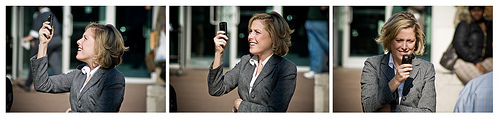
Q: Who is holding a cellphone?
A: The woman.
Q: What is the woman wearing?
A: A grey jacket.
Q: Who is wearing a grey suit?
A: The woman.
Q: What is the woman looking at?
A: Cellphone.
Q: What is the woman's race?
A: White.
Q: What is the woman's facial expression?
A: Smiling.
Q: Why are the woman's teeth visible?
A: She is smiling.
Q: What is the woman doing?
A: Taking a selfie.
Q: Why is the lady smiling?
A: For the photo.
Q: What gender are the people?
A: Female.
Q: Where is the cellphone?
A: Woman's right hand.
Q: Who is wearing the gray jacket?
A: Woman with the cellphone.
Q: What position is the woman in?
A: Sitting.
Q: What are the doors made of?
A: Glass.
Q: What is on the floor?
A: Carpet.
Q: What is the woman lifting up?
A: A cell phone.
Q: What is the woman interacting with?
A: A cell phone.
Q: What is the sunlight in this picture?
A: Bright.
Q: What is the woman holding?
A: A phone.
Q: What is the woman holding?
A: A cellphone.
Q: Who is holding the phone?
A: A woman.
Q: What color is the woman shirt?
A: White.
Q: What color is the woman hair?
A: Blonde.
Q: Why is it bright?
A: Sunny day.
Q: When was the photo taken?
A: Daytime.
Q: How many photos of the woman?
A: Three.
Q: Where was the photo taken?
A: Outside a building.